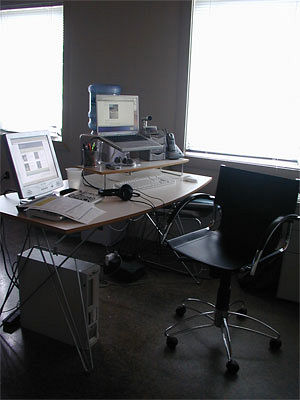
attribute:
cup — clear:
[64, 165, 85, 191]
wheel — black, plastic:
[224, 357, 240, 377]